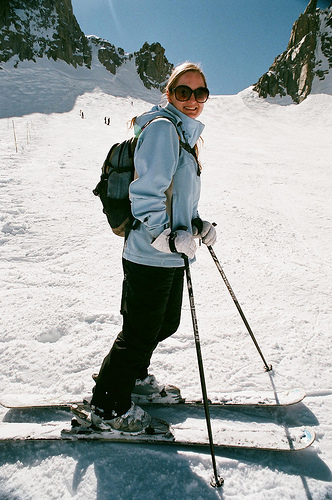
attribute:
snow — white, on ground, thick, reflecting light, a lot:
[1, 68, 330, 498]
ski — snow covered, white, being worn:
[1, 422, 315, 451]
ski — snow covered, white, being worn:
[0, 391, 306, 410]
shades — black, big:
[171, 85, 210, 104]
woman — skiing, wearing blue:
[92, 62, 217, 436]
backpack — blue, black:
[94, 137, 137, 237]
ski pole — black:
[169, 226, 224, 488]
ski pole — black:
[192, 217, 274, 373]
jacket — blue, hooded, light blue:
[122, 102, 205, 269]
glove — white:
[151, 227, 199, 259]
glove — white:
[201, 221, 218, 247]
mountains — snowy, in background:
[0, 0, 331, 104]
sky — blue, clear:
[71, 1, 312, 98]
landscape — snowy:
[0, 1, 331, 500]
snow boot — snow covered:
[92, 403, 169, 438]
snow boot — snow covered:
[131, 375, 181, 406]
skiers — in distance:
[78, 110, 85, 120]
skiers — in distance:
[104, 116, 112, 125]